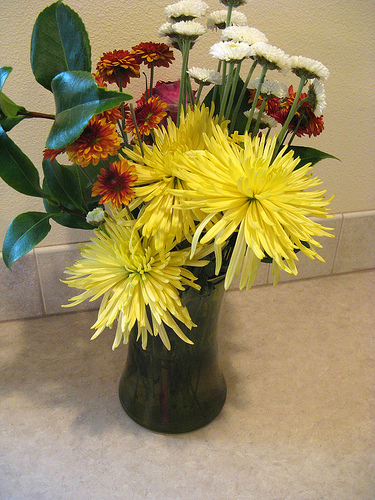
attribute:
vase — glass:
[116, 263, 225, 424]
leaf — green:
[57, 83, 120, 132]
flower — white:
[169, 19, 207, 36]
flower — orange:
[88, 161, 138, 213]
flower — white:
[289, 54, 327, 78]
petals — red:
[50, 210, 200, 349]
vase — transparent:
[113, 232, 230, 436]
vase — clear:
[98, 265, 245, 443]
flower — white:
[208, 37, 256, 63]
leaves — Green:
[53, 80, 101, 122]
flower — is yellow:
[71, 213, 180, 313]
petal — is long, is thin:
[139, 273, 158, 299]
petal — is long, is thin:
[148, 268, 174, 288]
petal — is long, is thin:
[116, 282, 122, 305]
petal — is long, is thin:
[91, 264, 125, 276]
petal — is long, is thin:
[158, 262, 183, 279]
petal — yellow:
[242, 213, 253, 248]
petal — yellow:
[253, 198, 271, 226]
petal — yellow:
[257, 223, 272, 258]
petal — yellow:
[200, 197, 238, 212]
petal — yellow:
[272, 189, 295, 202]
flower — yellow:
[177, 130, 337, 286]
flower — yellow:
[64, 214, 203, 348]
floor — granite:
[236, 306, 369, 488]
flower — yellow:
[99, 58, 322, 262]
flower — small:
[185, 67, 224, 86]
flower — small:
[289, 53, 328, 80]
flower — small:
[207, 40, 253, 63]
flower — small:
[171, 19, 205, 35]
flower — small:
[164, 0, 209, 20]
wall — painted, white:
[1, 3, 373, 252]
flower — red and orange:
[132, 39, 176, 71]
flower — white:
[208, 39, 252, 64]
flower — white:
[285, 55, 331, 80]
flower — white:
[306, 77, 325, 114]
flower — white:
[185, 65, 223, 84]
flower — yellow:
[58, 102, 334, 341]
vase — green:
[115, 152, 236, 436]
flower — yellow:
[168, 116, 341, 303]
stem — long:
[178, 44, 189, 112]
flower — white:
[292, 52, 329, 85]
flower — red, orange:
[90, 159, 139, 209]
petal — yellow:
[184, 65, 199, 79]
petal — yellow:
[309, 57, 315, 71]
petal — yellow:
[233, 44, 239, 61]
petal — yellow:
[186, 24, 189, 34]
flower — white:
[109, 224, 239, 436]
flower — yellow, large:
[174, 122, 333, 290]